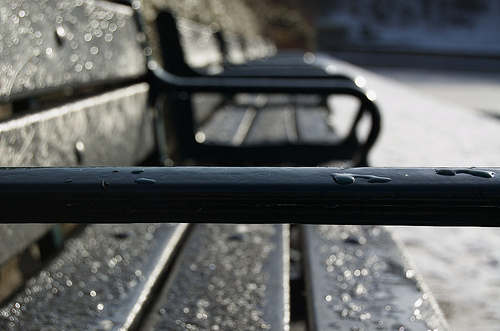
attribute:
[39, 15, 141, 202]
screws — dark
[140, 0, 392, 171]
benches — empty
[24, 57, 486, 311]
benches — lined up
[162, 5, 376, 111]
benches — wet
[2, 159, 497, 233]
rail — black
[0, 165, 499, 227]
bar — black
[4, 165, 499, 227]
arm rest — black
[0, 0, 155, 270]
chair back — wet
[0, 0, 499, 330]
benches — wet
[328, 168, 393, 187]
water — drops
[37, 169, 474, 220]
bar — black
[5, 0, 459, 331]
bench — soaked, empty, gray, chair, wet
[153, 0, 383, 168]
bench — armrest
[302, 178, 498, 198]
drops — clear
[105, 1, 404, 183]
benches — dark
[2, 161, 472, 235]
arm rest — black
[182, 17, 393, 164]
chair — armrest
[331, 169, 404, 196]
drops — rain